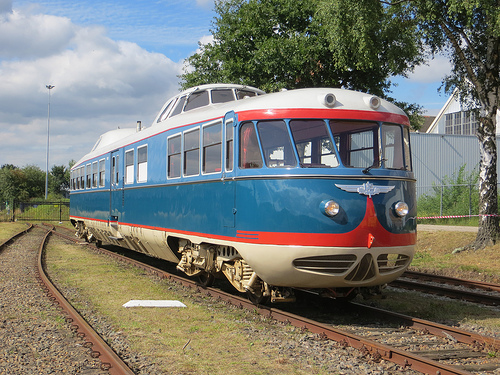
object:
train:
[69, 82, 420, 305]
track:
[311, 300, 500, 374]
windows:
[445, 114, 453, 135]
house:
[425, 73, 493, 135]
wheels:
[191, 240, 218, 289]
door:
[108, 151, 121, 233]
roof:
[148, 78, 259, 127]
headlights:
[393, 200, 411, 219]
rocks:
[50, 350, 72, 374]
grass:
[118, 302, 142, 319]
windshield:
[328, 120, 379, 167]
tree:
[182, 0, 426, 128]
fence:
[422, 130, 472, 177]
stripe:
[117, 221, 178, 233]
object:
[122, 299, 187, 308]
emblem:
[335, 177, 396, 198]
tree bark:
[474, 152, 496, 206]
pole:
[43, 88, 53, 206]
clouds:
[13, 21, 103, 92]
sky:
[65, 4, 197, 29]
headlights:
[321, 200, 342, 217]